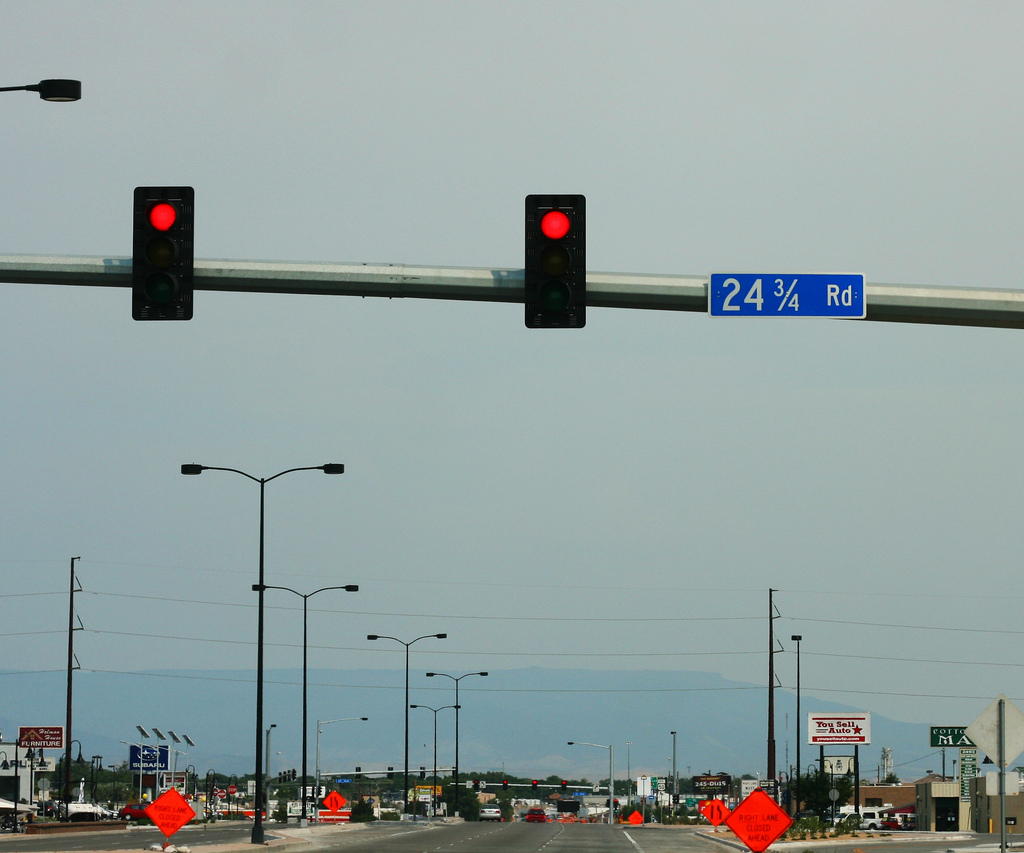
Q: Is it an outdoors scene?
A: Yes, it is outdoors.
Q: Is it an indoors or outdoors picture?
A: It is outdoors.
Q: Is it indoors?
A: No, it is outdoors.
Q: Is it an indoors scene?
A: No, it is outdoors.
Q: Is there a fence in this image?
A: No, there are no fences.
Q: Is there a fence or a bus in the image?
A: No, there are no fences or buses.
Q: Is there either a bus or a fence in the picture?
A: No, there are no fences or buses.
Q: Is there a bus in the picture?
A: No, there are no buses.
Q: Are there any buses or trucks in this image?
A: No, there are no buses or trucks.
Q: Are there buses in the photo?
A: No, there are no buses.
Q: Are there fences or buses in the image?
A: No, there are no buses or fences.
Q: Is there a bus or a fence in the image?
A: No, there are no buses or fences.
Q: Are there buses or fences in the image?
A: No, there are no buses or fences.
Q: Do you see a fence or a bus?
A: No, there are no buses or fences.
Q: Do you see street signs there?
A: Yes, there is a street sign.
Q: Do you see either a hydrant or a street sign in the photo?
A: Yes, there is a street sign.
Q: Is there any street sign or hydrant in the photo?
A: Yes, there is a street sign.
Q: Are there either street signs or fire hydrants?
A: Yes, there is a street sign.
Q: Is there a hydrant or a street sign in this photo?
A: Yes, there is a street sign.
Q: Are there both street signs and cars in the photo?
A: Yes, there are both a street sign and a car.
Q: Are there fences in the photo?
A: No, there are no fences.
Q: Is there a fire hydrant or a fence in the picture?
A: No, there are no fences or fire hydrants.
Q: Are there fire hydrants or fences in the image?
A: No, there are no fences or fire hydrants.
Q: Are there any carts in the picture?
A: No, there are no carts.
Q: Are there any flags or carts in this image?
A: No, there are no carts or flags.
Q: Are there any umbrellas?
A: No, there are no umbrellas.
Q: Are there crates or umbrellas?
A: No, there are no umbrellas or crates.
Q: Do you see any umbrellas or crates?
A: No, there are no umbrellas or crates.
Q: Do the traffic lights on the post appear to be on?
A: Yes, the traffic lights are on.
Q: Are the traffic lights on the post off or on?
A: The traffic lights are on.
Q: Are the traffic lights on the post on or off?
A: The traffic lights are on.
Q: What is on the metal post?
A: The traffic lights are on the post.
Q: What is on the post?
A: The traffic lights are on the post.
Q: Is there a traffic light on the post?
A: Yes, there are traffic lights on the post.